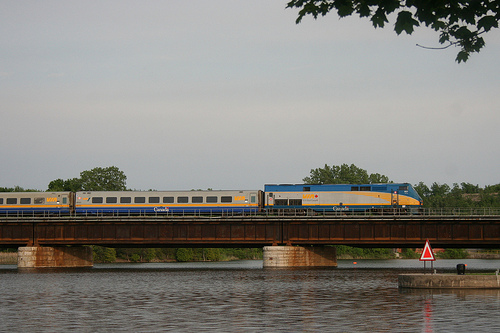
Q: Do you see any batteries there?
A: No, there are no batteries.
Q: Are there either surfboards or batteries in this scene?
A: No, there are no batteries or surfboards.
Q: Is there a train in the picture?
A: Yes, there is a train.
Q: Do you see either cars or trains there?
A: Yes, there is a train.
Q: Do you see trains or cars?
A: Yes, there is a train.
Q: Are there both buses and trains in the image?
A: No, there is a train but no buses.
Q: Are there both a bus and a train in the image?
A: No, there is a train but no buses.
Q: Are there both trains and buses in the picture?
A: No, there is a train but no buses.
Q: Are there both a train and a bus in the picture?
A: No, there is a train but no buses.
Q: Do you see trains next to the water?
A: Yes, there is a train next to the water.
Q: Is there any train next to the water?
A: Yes, there is a train next to the water.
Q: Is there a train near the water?
A: Yes, there is a train near the water.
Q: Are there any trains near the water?
A: Yes, there is a train near the water.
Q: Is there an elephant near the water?
A: No, there is a train near the water.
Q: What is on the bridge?
A: The train is on the bridge.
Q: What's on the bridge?
A: The train is on the bridge.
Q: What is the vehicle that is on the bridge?
A: The vehicle is a train.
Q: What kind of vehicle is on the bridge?
A: The vehicle is a train.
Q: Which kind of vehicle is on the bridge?
A: The vehicle is a train.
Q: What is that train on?
A: The train is on the bridge.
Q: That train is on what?
A: The train is on the bridge.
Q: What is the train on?
A: The train is on the bridge.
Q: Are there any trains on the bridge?
A: Yes, there is a train on the bridge.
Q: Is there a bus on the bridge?
A: No, there is a train on the bridge.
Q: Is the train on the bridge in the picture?
A: Yes, the train is on the bridge.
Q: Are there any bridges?
A: Yes, there is a bridge.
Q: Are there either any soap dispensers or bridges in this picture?
A: Yes, there is a bridge.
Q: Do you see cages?
A: No, there are no cages.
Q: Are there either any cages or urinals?
A: No, there are no cages or urinals.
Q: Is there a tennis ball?
A: No, there are no tennis balls.